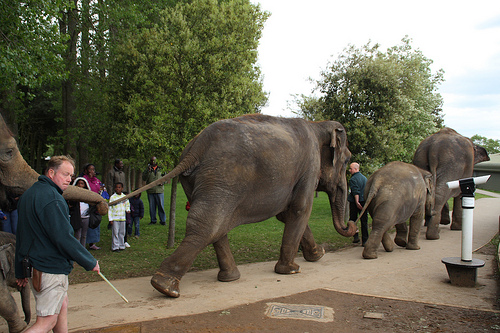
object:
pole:
[461, 197, 474, 262]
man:
[14, 154, 100, 331]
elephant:
[0, 117, 110, 331]